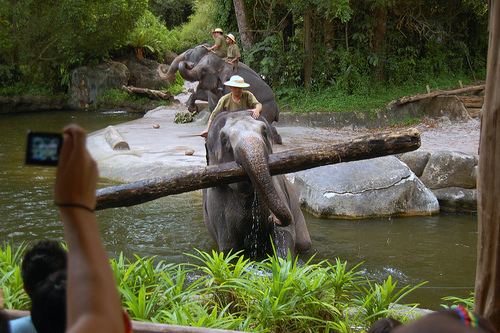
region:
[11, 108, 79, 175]
a camera taking a picture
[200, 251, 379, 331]
gree tufts of grass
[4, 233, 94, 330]
two childrens brown hair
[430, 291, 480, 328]
a small colorful ribbon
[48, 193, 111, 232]
black strap on wrist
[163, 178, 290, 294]
water dripping from elephant mouth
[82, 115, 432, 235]
elephant carrying a log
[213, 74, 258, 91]
a brown straw hat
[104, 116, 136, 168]
log stuck in cement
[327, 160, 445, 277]
large rock near water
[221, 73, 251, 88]
safari hat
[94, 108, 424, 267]
elephant carrying a tree log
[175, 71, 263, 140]
elephant rider holding a stick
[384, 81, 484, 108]
fallen tree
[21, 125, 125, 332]
arm holding up cell phone camera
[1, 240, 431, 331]
lush forest vegetation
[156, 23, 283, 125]
two people riding elephants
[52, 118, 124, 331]
wrist band on woman's arm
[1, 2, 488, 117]
dense, green forest vegetation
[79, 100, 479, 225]
flat rock area on the opposite bank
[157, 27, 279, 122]
two elephants in the background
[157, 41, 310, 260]
three elephants with riders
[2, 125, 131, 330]
people watching the elephants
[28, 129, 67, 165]
camera taking a video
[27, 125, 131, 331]
person shooting a video of the elephants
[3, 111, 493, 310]
murky, green river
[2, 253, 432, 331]
green plants between observers and elephant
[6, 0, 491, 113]
jungle area behind the elephants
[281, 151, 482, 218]
giant gray boulders to right of elephant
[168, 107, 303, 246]
a elephant with a log in its mouth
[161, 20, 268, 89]
two men sitting on elephants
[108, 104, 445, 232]
a elephant carrying a log in its mouth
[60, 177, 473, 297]
a small body of water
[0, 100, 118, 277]
a person holding camera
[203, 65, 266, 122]
a man wearing a straw hat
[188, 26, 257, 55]
two men wearing straw hats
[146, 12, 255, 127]
two elephants lifting up their front legs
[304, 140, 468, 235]
a large rock by water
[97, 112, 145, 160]
a log on the ground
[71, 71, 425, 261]
an elephant carrying a log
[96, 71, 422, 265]
a man riding an elephant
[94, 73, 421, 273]
an elephant carrying a log across water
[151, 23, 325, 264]
three humans riding elephants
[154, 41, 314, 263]
three large grey elephants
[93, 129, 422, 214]
a large log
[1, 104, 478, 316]
a dark colored stream of water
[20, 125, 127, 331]
a person taking a picture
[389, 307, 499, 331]
a person wearing a colorful bracelet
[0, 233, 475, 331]
green plants by the water